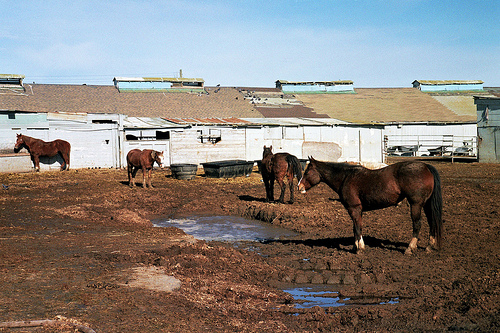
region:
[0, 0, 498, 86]
blue of daytime sky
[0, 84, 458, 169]
roof of horse barn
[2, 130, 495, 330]
horses on muddy terrain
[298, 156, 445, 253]
side of standing horse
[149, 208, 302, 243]
pool of water in dirt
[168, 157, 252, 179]
round and square tubs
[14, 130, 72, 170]
horse standing next to barn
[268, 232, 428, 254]
shadow of horse on mud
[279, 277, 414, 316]
puddle of water in dirt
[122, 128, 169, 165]
opening in side of barn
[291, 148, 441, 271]
this is a horse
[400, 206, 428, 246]
these are the legs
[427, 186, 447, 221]
this is the tail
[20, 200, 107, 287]
this is the ground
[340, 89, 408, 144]
this is the stable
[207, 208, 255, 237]
this is mud in front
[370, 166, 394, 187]
the horse is brown in color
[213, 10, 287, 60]
this is the sky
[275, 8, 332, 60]
the sky is clear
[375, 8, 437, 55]
the sky is blue in color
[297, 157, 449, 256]
Brown horse covered with mad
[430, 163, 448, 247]
Black tail of a horse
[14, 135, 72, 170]
Horse standing beside building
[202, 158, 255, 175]
Black container in a ranch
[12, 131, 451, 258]
Horses standing in a ranch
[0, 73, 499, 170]
White building in a ranch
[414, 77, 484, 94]
Blue building in the distance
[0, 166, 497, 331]
Ground covered with mad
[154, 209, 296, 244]
A pool of dirty water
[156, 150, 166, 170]
Horse with a white face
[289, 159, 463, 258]
the horse is brown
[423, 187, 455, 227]
the tail is black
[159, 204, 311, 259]
the water is dirty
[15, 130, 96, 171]
the horse is brown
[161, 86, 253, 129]
the roof is grey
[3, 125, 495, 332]
the ground is muddy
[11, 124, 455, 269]
the horses are four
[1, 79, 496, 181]
the structures are woden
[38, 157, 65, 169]
shadow is on the wall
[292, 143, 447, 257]
small baby horse in mud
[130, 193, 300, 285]
large muddy pit by dry land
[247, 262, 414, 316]
puddles in the mud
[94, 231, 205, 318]
patch of dry land in the mud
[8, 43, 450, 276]
4 horses looking random directions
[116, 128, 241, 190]
small pony by a food bin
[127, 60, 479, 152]
beat up horse stable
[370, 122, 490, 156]
horse entrance metal fence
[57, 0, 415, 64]
blue sky's with clouds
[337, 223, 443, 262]
white feet on the horse